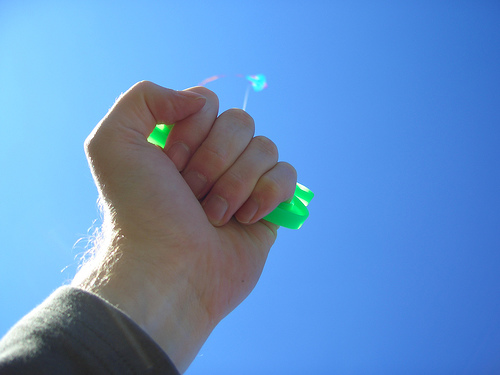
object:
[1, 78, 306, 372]
man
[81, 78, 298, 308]
hand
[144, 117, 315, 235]
knife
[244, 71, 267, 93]
kite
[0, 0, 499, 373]
sky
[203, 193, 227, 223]
fingernail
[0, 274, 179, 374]
shirt sleeve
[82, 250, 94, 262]
hairs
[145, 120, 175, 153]
circle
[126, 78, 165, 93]
knuckles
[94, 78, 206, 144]
thumb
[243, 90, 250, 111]
kite string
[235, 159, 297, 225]
pinky finger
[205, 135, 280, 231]
ring finger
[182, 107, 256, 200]
middle finger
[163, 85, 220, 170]
index finger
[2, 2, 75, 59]
light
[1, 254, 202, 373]
arm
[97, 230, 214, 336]
wrist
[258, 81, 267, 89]
part